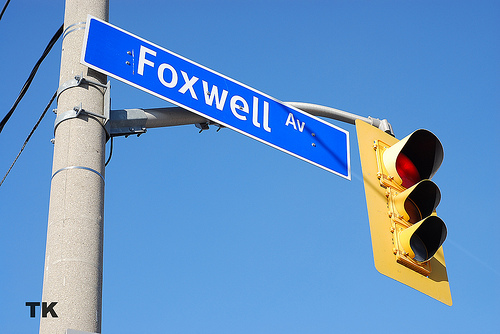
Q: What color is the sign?
A: Blue.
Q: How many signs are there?
A: One.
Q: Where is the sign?
A: On the pole.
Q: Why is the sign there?
A: To tell people what street they are on.